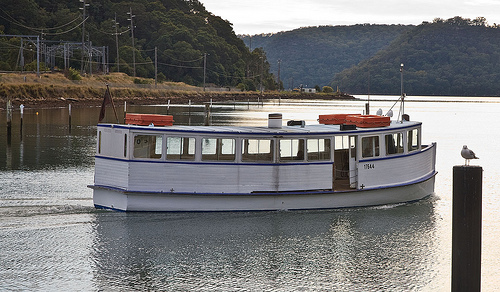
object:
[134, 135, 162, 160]
window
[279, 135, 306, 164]
window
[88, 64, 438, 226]
ship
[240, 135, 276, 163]
window